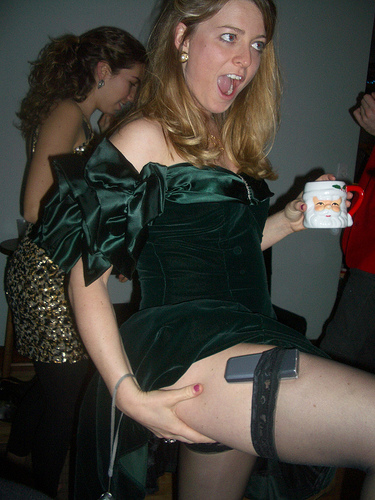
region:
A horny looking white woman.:
[24, 1, 372, 499]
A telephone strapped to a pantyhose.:
[223, 345, 300, 383]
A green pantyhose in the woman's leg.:
[250, 343, 373, 496]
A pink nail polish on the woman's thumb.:
[191, 382, 201, 393]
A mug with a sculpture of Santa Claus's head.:
[301, 178, 365, 228]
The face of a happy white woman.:
[112, 1, 284, 179]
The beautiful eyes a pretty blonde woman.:
[215, 24, 266, 52]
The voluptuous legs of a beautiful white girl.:
[148, 340, 371, 498]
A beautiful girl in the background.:
[1, 23, 152, 498]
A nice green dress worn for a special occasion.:
[26, 133, 332, 494]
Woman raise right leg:
[32, 2, 373, 499]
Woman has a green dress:
[31, 2, 371, 491]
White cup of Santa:
[294, 171, 364, 238]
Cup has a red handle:
[297, 177, 367, 232]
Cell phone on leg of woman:
[220, 345, 307, 384]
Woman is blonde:
[82, 0, 298, 212]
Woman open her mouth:
[129, 2, 301, 190]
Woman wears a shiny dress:
[4, 18, 140, 490]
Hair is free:
[100, 2, 306, 250]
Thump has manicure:
[182, 377, 207, 402]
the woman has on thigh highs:
[167, 343, 370, 498]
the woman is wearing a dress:
[28, 131, 335, 499]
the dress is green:
[27, 131, 342, 496]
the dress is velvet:
[33, 130, 353, 498]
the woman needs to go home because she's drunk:
[37, 1, 374, 498]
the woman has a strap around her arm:
[88, 370, 138, 499]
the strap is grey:
[98, 368, 141, 499]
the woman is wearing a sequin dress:
[0, 98, 106, 368]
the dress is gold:
[2, 98, 105, 372]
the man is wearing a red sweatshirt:
[336, 131, 374, 276]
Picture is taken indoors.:
[22, 14, 298, 464]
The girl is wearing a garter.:
[222, 329, 275, 481]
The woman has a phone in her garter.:
[215, 351, 298, 399]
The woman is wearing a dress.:
[136, 197, 247, 288]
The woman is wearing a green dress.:
[165, 244, 266, 296]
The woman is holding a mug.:
[291, 153, 360, 255]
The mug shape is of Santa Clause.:
[297, 166, 371, 238]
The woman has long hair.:
[156, 65, 295, 181]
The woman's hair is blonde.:
[130, 5, 313, 180]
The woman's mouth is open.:
[212, 71, 245, 104]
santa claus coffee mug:
[291, 170, 369, 243]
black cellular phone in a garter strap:
[222, 348, 319, 393]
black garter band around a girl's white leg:
[223, 333, 314, 469]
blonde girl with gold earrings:
[146, 2, 294, 156]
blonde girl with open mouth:
[145, 4, 310, 188]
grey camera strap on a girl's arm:
[83, 368, 169, 491]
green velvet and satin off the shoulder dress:
[52, 98, 298, 421]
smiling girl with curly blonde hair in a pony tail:
[13, 19, 152, 241]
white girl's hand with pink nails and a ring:
[129, 378, 225, 470]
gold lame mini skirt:
[9, 211, 93, 403]